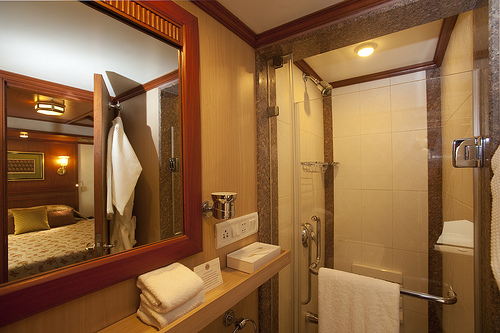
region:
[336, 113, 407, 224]
tiles on the wall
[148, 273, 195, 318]
A towel on the shelf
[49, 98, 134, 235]
A mirror in the bathroom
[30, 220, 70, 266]
A bed in the room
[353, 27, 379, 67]
Light bulb in the ceiling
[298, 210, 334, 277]
Metal bars on the wall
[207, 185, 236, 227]
Lamp in the photo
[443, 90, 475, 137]
A wall in the room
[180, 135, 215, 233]
Wooden frame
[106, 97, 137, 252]
White robe hanging on back of bathroom door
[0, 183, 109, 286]
Bed reflected in bathroom mirror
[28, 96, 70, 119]
Ceiling light reflected in bathroom mirror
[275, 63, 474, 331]
Glass shower door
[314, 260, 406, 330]
White towel hanging on shower door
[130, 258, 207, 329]
White towels folded on shelf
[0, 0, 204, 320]
Wood framed bathroom mirror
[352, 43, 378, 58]
Round light in ceiling of the shower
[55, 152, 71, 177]
Wall mounted light fixture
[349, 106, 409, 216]
White tile in shower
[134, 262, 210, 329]
a stack of white towels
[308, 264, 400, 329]
a white towel hanging on a rod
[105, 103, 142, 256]
a white towel hanging on a door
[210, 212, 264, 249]
a group of light switches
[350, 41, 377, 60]
a light in the ceiling of a bathroom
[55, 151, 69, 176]
a lamp on a wall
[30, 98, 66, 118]
a lamp on the ceiling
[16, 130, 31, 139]
a lamp on the ceiling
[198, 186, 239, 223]
a lamp on the wall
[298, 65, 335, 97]
a metal shower head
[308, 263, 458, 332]
white towel hanging on a metal rack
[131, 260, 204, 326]
two white towels folded on a shelf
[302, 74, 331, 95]
silver shower head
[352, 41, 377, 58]
light fixture in bathroom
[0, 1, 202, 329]
mirror with a wood frame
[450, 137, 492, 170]
shiny silver metal hinge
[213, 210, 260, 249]
white electric outlet on wall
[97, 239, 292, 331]
wood shelf on bathroom wall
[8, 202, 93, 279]
reflection of bed with pillows on top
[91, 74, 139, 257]
reflection of towel hanging on door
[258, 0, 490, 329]
roomy box-like shower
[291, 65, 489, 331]
glass shower door on a hinge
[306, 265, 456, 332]
white towel hung from a towel bar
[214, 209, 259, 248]
long white panel on wall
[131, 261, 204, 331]
folded white towels on a shelf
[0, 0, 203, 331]
part of a mirror with a thick wooden frame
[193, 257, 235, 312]
small sign on shelf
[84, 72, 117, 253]
open door reflected in mirror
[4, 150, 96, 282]
framed piece above bed reflected in mirror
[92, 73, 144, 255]
white robe hung on hook behind door